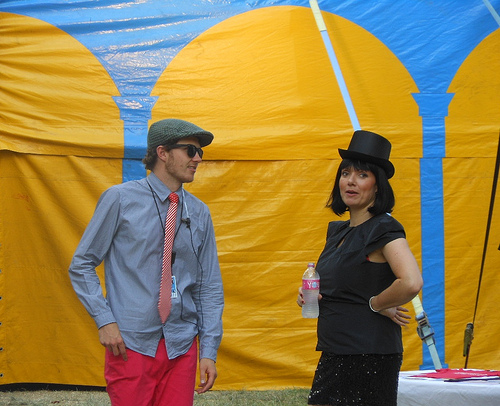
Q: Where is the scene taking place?
A: Outside circus tent.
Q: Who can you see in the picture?
A: A man and a woman.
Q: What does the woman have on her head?
A: A top hat.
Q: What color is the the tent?
A: Blue and yellow.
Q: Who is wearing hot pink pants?
A: The man.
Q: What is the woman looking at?
A: The camera.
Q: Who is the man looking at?
A: The woman.